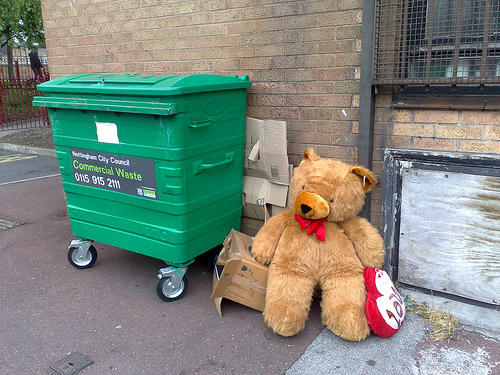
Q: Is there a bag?
A: No, there are no bags.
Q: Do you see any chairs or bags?
A: No, there are no bags or chairs.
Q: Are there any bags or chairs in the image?
A: No, there are no bags or chairs.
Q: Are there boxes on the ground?
A: Yes, there is a box on the ground.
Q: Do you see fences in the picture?
A: Yes, there is a fence.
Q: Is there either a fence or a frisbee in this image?
A: Yes, there is a fence.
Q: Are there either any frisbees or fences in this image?
A: Yes, there is a fence.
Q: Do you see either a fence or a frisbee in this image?
A: Yes, there is a fence.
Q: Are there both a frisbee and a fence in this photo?
A: No, there is a fence but no frisbees.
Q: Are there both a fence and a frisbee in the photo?
A: No, there is a fence but no frisbees.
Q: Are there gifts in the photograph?
A: No, there are no gifts.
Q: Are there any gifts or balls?
A: No, there are no gifts or balls.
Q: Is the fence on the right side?
A: No, the fence is on the left of the image.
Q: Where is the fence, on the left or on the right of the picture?
A: The fence is on the left of the image.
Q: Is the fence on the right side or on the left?
A: The fence is on the left of the image.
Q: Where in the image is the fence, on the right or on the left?
A: The fence is on the left of the image.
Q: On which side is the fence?
A: The fence is on the left of the image.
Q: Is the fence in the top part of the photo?
A: Yes, the fence is in the top of the image.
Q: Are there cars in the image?
A: No, there are no cars.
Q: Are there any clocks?
A: No, there are no clocks.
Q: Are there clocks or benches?
A: No, there are no clocks or benches.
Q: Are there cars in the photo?
A: No, there are no cars.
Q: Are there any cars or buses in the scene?
A: No, there are no cars or buses.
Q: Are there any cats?
A: No, there are no cats.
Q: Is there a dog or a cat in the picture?
A: No, there are no cats or dogs.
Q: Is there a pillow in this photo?
A: Yes, there is a pillow.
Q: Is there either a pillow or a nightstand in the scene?
A: Yes, there is a pillow.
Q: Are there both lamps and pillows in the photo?
A: No, there is a pillow but no lamps.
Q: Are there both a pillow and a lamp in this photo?
A: No, there is a pillow but no lamps.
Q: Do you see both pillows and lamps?
A: No, there is a pillow but no lamps.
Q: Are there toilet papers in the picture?
A: No, there are no toilet papers.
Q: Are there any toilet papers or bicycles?
A: No, there are no toilet papers or bicycles.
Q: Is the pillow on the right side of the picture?
A: Yes, the pillow is on the right of the image.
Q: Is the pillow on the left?
A: No, the pillow is on the right of the image.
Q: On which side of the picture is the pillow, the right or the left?
A: The pillow is on the right of the image.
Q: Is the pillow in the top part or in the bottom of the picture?
A: The pillow is in the bottom of the image.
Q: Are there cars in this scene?
A: No, there are no cars.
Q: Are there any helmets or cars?
A: No, there are no cars or helmets.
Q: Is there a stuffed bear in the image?
A: Yes, there is a stuffed bear.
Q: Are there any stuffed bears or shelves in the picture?
A: Yes, there is a stuffed bear.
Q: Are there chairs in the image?
A: No, there are no chairs.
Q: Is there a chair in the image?
A: No, there are no chairs.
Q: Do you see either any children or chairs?
A: No, there are no chairs or children.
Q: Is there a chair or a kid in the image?
A: No, there are no chairs or children.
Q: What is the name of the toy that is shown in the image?
A: The toy is a stuffed bear.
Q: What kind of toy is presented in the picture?
A: The toy is a stuffed bear.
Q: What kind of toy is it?
A: The toy is a stuffed bear.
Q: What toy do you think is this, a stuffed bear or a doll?
A: That is a stuffed bear.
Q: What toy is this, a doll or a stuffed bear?
A: That is a stuffed bear.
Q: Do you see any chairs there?
A: No, there are no chairs.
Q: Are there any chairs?
A: No, there are no chairs.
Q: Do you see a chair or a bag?
A: No, there are no chairs or bags.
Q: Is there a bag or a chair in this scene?
A: No, there are no chairs or bags.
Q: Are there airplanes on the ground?
A: No, there is a box on the ground.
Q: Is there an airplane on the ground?
A: No, there is a box on the ground.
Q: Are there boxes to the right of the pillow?
A: No, the box is to the left of the pillow.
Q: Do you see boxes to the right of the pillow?
A: No, the box is to the left of the pillow.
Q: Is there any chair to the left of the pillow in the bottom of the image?
A: No, there is a box to the left of the pillow.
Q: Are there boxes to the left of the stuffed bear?
A: Yes, there is a box to the left of the stuffed bear.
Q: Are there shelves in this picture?
A: No, there are no shelves.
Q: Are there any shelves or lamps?
A: No, there are no shelves or lamps.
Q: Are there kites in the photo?
A: No, there are no kites.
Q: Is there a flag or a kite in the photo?
A: No, there are no kites or flags.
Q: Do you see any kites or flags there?
A: No, there are no kites or flags.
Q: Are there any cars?
A: No, there are no cars.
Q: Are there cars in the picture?
A: No, there are no cars.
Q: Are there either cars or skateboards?
A: No, there are no cars or skateboards.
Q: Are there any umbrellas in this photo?
A: No, there are no umbrellas.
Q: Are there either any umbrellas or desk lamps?
A: No, there are no umbrellas or desk lamps.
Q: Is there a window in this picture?
A: Yes, there is a window.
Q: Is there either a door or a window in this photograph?
A: Yes, there is a window.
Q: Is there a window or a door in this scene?
A: Yes, there is a window.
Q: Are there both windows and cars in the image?
A: No, there is a window but no cars.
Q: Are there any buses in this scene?
A: No, there are no buses.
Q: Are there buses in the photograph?
A: No, there are no buses.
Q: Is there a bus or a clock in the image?
A: No, there are no buses or clocks.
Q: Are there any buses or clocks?
A: No, there are no buses or clocks.